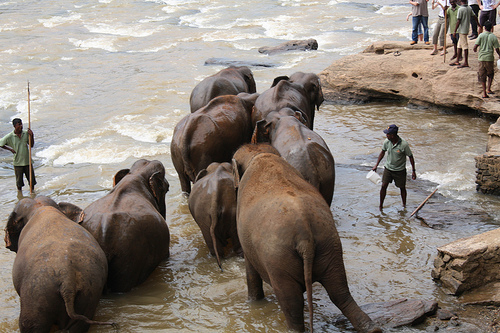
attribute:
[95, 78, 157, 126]
water — brown